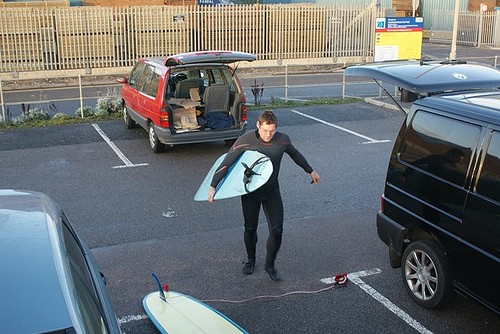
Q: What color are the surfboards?
A: White and blue.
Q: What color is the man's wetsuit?
A: Black.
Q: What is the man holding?
A: A surfboard.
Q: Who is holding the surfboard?
A: The man.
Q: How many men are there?
A: One.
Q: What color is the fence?
A: Brown.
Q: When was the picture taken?
A: Daytime.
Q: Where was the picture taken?
A: On the street.